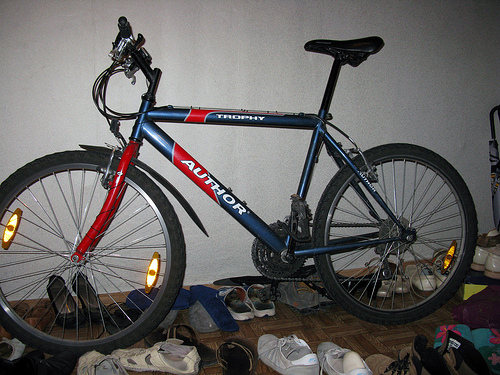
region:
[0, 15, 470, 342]
the bicycle is against the wall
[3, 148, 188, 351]
the tire is made of rubber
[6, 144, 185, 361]
the tire is black in color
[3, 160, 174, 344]
the rim is made of metal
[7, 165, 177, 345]
the rim is made of steel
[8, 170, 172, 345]
the wheel is held by spokes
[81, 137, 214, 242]
the fender is made of metal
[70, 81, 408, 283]
the body is made of metal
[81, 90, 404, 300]
the bike is painted blue and red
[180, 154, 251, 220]
lettering is on the bike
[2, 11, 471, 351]
bike leaning against the wall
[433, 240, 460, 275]
yellow reflector on the spokes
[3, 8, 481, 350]
red and blue bike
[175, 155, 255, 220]
white writing on the bike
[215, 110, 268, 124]
white writing in all caps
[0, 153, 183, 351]
silver spokes on the wheel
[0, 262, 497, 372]
several pairs of shoes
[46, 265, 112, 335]
a pair of black heels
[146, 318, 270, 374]
a pair of sandals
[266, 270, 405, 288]
chain on the bike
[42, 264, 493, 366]
shoes on the floor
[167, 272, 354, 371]
shoes on the floor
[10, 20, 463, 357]
a bike leaning on the wall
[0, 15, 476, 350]
the bike against the wall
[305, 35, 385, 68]
the seat on the bike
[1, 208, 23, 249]
the light on the spokes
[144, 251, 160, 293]
the light on the spokes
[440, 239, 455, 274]
the light on the spokes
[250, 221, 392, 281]
the chain on the bike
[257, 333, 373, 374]
the pair of gray shoes on the ground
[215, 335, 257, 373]
the slipper on the ground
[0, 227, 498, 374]
the footwear around the bike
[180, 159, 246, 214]
the letters on the bike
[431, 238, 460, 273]
yellow reflector on the wheel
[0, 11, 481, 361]
blue and red bike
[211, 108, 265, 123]
white writing in all caps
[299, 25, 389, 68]
black seat on the bike